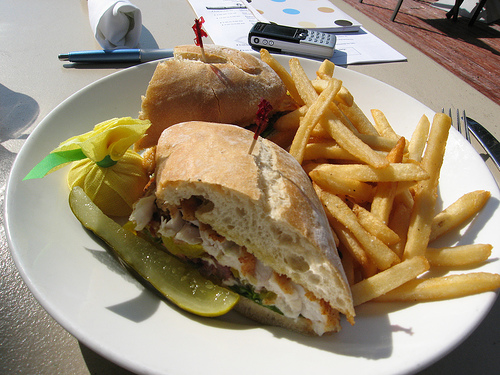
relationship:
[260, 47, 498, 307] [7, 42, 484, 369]
french fries on plate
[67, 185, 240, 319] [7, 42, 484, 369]
pickle on plate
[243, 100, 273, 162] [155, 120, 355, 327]
tooth pick in bread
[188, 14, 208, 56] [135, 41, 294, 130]
tooth pick in sandwich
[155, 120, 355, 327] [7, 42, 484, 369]
bread on plate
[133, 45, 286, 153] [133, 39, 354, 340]
bread on sandwiches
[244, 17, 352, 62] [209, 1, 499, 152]
mobile phone on table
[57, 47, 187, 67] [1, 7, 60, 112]
pen on table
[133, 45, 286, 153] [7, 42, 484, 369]
bread on plate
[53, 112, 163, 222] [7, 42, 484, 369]
sack on plate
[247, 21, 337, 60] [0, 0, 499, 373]
cell phone on desk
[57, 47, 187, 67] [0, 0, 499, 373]
pen on desk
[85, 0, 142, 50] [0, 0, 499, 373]
napkin on desk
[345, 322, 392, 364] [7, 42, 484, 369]
shadow on plate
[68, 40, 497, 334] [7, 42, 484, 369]
food on plate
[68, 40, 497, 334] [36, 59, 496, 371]
food on plate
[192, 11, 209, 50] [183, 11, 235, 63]
plastic top on toothpick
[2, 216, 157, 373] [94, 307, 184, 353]
plate edge on plate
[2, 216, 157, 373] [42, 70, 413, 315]
plate edge on plate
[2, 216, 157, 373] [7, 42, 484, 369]
plate edge on plate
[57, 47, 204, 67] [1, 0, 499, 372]
pen on table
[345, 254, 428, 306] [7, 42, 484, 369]
fry on plate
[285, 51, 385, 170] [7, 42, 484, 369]
fry on plate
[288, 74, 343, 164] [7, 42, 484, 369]
fry on plate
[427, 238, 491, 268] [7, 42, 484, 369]
fry on plate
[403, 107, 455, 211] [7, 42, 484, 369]
fry on plate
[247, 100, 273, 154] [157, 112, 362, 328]
tooth pick in bread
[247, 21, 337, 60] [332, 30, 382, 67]
cell phone on paper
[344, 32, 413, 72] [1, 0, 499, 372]
paper on table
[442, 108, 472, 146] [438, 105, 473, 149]
fork on fork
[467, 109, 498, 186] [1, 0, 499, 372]
knife on table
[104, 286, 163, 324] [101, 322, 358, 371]
shadow on plate